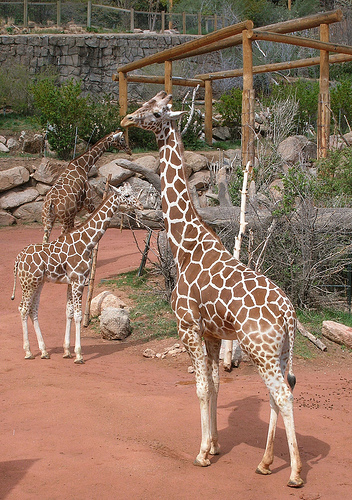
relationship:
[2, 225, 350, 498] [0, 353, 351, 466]
floor has dirt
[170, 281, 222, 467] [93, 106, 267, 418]
front legs of giraffe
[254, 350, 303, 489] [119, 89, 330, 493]
legs of giraffe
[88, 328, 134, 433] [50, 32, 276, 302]
shadow of a giraffe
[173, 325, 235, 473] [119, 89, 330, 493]
legs on giraffe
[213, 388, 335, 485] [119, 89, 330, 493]
shadow of giraffe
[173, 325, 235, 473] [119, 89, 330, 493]
legs of giraffe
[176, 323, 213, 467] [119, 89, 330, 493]
front leg of giraffe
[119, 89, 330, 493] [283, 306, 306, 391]
giraffe has tail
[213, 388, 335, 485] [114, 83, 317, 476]
shadow of giraffe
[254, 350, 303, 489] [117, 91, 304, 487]
legs of giraffe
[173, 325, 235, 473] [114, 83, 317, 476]
legs on giraffe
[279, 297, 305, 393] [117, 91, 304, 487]
tail on giraffe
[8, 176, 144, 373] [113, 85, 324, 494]
baby giraffe next to mom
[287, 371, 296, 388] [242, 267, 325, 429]
turf on tail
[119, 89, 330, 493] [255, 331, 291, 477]
giraffe has back leg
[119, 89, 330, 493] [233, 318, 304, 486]
giraffe has back leg